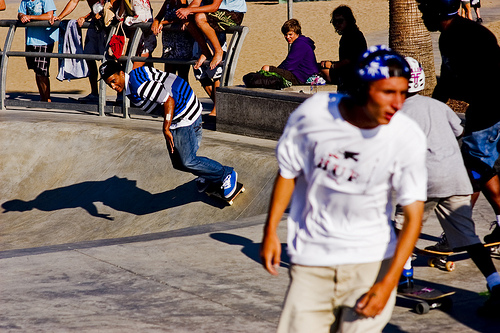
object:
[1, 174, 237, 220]
shadow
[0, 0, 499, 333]
pavement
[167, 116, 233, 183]
jeans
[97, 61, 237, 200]
man